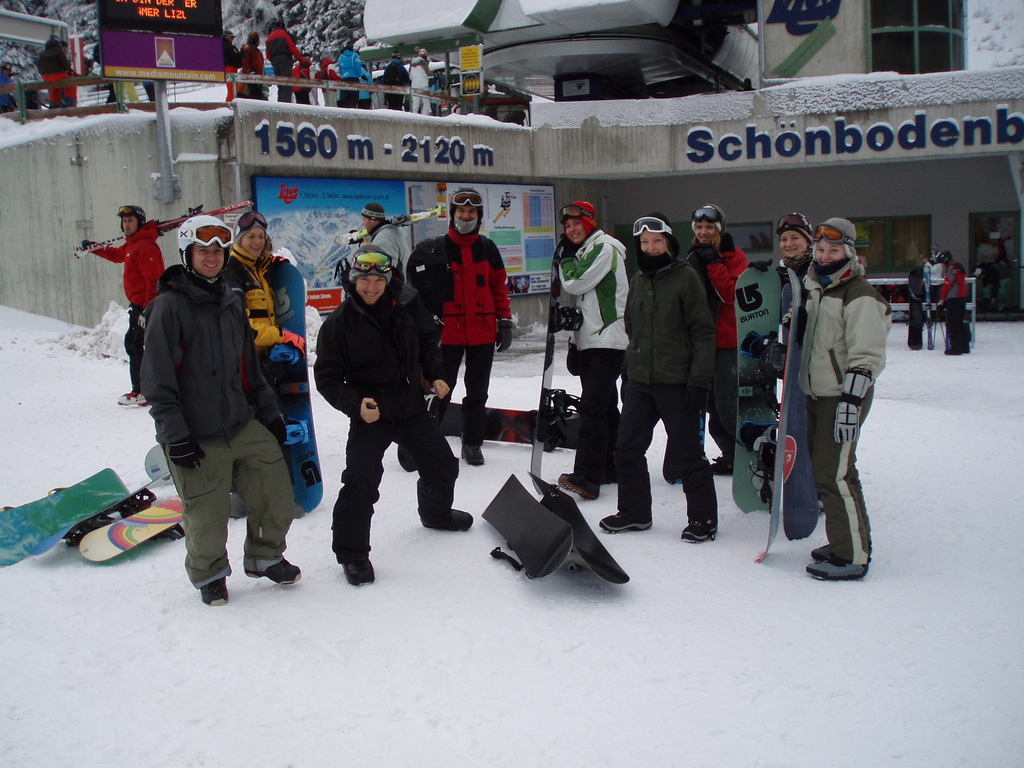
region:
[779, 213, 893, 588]
Woman holding snowboard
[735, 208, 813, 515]
Man holding green snowboard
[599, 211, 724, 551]
Person wearing snow goggles on head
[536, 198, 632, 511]
Person wearing green and white jacket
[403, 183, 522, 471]
Person wearing red and black jacket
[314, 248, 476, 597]
Man wearing all black snow gear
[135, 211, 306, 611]
Man wearing white hat and snow goggles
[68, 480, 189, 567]
Snowboard laying on snow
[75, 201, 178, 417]
Man wearing a red jacket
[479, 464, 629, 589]
Black snowboards laying in snow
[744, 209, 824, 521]
person standing on snow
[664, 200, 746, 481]
person standing on snow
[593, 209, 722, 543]
person standing on snow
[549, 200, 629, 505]
person standing on snow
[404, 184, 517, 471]
person standing on snow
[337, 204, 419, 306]
person standing on snow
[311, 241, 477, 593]
person standing on snow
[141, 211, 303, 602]
person standing on snow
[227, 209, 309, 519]
person standing on snow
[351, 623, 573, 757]
white snow in front of people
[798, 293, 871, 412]
man has grey coat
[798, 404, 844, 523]
black and grey pants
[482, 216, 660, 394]
green and white coat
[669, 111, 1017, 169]
blue sign behind people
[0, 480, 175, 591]
snowboards are behind people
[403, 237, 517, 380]
red and black coat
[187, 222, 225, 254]
man has orange goggles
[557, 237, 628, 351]
a person wearing a green and white coat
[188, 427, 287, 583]
a man wearing green pants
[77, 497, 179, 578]
a multicolored snowboard on the ground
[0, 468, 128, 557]
a green snowboard on the ground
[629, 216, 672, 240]
a person with white goggles on their head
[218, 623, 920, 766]
snow covering the ground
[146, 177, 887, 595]
several people standing together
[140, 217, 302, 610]
white person is posing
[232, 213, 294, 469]
white person is posing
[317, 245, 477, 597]
white person is posing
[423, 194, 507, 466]
white person is posing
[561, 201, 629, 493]
white person is posing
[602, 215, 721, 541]
white person is posing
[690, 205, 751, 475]
white person is posing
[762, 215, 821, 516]
white person is posing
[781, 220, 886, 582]
white person is posing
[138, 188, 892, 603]
a group of skiers and snowboarders are posing together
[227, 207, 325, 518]
the woman is wearing a yellow jacket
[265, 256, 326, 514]
the woman is holding a blue snowhboard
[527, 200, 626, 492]
a woman is wearing a green and white jacket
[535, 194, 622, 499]
the woman is wearing a red hat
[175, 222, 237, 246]
there is a pair of orange goggles on the white helmet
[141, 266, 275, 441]
the man in front is wearing a dark grey jacket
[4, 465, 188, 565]
several snowboards are on the ground behind the group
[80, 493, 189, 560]
one snow board is white with rainbows on it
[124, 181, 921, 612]
Snowboarders and skiers posing for picture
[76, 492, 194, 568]
Yellow colored snow board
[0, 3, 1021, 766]
Ski resort with several people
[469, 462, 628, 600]
Two snow boards laying on snow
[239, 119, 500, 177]
Blue text sign displaying altitude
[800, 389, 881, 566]
Gray snow pants with white stripe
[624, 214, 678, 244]
White snow goggles with black shade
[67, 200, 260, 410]
Skier walking with skis over shoulder